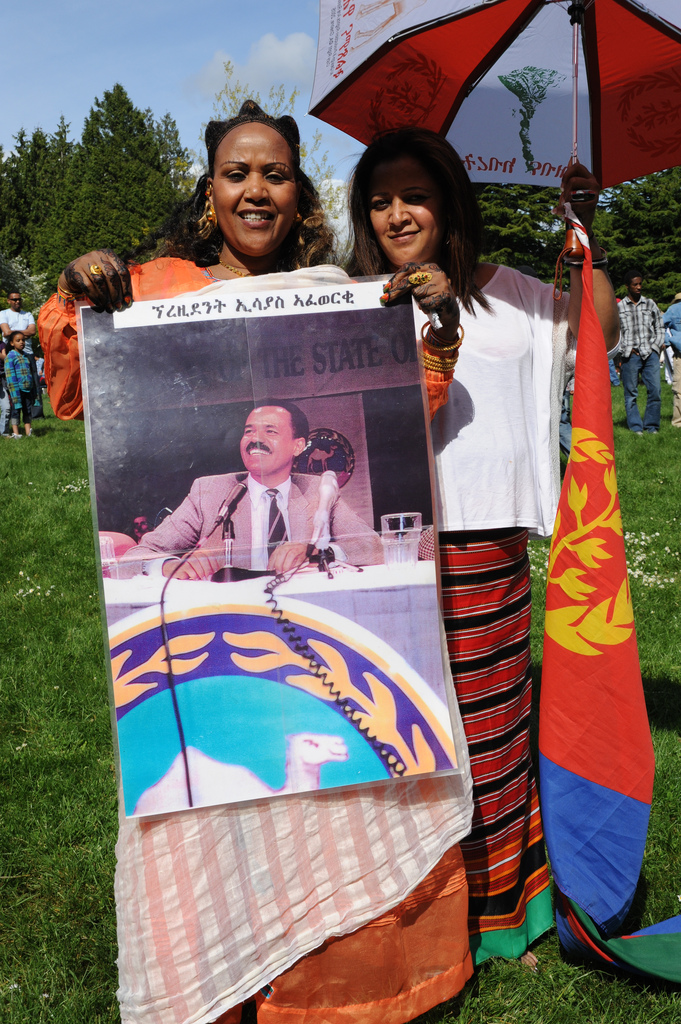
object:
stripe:
[438, 529, 528, 566]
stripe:
[436, 559, 528, 589]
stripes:
[469, 827, 542, 880]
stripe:
[446, 611, 532, 662]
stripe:
[462, 681, 528, 720]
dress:
[404, 266, 564, 957]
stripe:
[472, 769, 534, 822]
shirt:
[413, 265, 571, 536]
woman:
[41, 95, 469, 1023]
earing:
[195, 211, 209, 239]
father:
[0, 281, 43, 420]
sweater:
[2, 347, 43, 413]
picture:
[76, 277, 463, 818]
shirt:
[618, 298, 665, 352]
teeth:
[240, 206, 273, 222]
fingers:
[379, 271, 429, 306]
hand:
[52, 247, 138, 304]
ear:
[192, 183, 214, 229]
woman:
[345, 118, 640, 984]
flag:
[535, 205, 681, 979]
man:
[613, 273, 664, 438]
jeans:
[622, 347, 659, 423]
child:
[4, 328, 43, 438]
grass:
[0, 445, 114, 1018]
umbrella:
[306, 0, 681, 181]